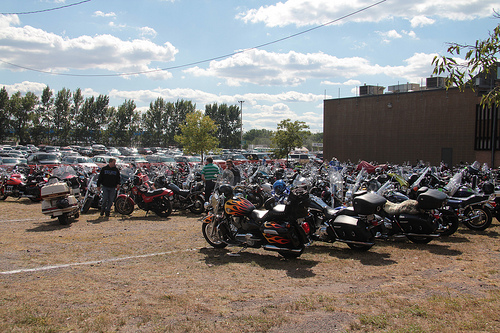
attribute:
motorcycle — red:
[115, 165, 179, 227]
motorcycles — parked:
[0, 155, 500, 260]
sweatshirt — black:
[94, 166, 123, 186]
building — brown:
[284, 61, 497, 218]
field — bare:
[19, 201, 395, 323]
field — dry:
[1, 190, 495, 331]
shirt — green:
[203, 165, 214, 180]